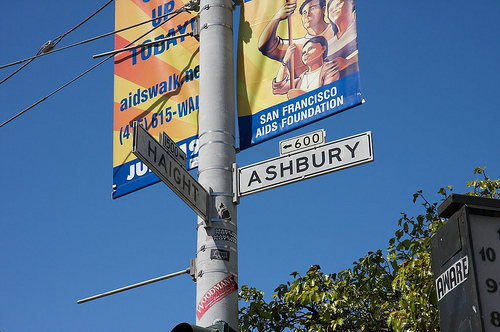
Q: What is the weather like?
A: It is clear.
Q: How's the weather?
A: It is clear.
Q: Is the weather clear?
A: Yes, it is clear.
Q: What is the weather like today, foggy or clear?
A: It is clear.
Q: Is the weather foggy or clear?
A: It is clear.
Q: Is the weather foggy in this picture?
A: No, it is clear.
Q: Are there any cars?
A: No, there are no cars.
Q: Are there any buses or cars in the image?
A: No, there are no cars or buses.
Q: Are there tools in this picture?
A: No, there are no tools.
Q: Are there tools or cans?
A: No, there are no tools or cans.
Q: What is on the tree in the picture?
A: The leaves are on the tree.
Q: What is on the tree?
A: The leaves are on the tree.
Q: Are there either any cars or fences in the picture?
A: No, there are no cars or fences.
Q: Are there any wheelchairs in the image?
A: No, there are no wheelchairs.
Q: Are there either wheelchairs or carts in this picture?
A: No, there are no wheelchairs or carts.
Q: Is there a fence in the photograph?
A: No, there are no fences.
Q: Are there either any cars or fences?
A: No, there are no fences or cars.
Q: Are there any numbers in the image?
A: Yes, there are numbers.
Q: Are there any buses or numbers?
A: Yes, there are numbers.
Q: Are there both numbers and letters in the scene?
A: Yes, there are both numbers and letters.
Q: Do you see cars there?
A: No, there are no cars.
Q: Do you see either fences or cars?
A: No, there are no cars or fences.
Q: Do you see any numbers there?
A: Yes, there are numbers.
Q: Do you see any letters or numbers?
A: Yes, there are numbers.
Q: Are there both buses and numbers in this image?
A: No, there are numbers but no buses.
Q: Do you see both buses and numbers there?
A: No, there are numbers but no buses.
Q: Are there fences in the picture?
A: No, there are no fences.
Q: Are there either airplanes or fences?
A: No, there are no fences or airplanes.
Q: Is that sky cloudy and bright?
A: No, the sky is bright but clear.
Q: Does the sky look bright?
A: Yes, the sky is bright.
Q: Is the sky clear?
A: Yes, the sky is clear.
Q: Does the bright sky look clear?
A: Yes, the sky is clear.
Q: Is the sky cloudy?
A: No, the sky is clear.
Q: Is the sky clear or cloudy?
A: The sky is clear.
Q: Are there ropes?
A: No, there are no ropes.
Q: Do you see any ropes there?
A: No, there are no ropes.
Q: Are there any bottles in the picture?
A: No, there are no bottles.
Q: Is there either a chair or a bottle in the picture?
A: No, there are no bottles or chairs.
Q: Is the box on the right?
A: Yes, the box is on the right of the image.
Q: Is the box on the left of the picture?
A: No, the box is on the right of the image.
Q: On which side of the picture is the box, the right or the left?
A: The box is on the right of the image.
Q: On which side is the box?
A: The box is on the right of the image.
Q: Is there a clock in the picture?
A: Yes, there is a clock.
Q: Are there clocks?
A: Yes, there is a clock.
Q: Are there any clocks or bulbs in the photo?
A: Yes, there is a clock.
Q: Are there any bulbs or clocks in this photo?
A: Yes, there is a clock.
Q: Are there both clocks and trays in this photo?
A: No, there is a clock but no trays.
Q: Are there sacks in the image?
A: No, there are no sacks.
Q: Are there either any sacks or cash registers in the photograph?
A: No, there are no sacks or cash registers.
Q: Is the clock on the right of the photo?
A: Yes, the clock is on the right of the image.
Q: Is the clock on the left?
A: No, the clock is on the right of the image.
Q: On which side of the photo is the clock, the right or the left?
A: The clock is on the right of the image.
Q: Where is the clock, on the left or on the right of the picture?
A: The clock is on the right of the image.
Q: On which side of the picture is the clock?
A: The clock is on the right of the image.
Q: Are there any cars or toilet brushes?
A: No, there are no cars or toilet brushes.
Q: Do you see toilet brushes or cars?
A: No, there are no cars or toilet brushes.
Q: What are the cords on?
A: The cords are on the pole.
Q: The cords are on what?
A: The cords are on the pole.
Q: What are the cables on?
A: The cords are on the pole.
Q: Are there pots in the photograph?
A: No, there are no pots.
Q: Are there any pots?
A: No, there are no pots.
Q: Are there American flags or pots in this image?
A: No, there are no pots or American flags.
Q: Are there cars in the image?
A: No, there are no cars.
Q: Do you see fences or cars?
A: No, there are no cars or fences.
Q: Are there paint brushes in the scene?
A: No, there are no paint brushes.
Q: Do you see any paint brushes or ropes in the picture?
A: No, there are no paint brushes or ropes.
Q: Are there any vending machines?
A: No, there are no vending machines.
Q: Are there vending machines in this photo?
A: No, there are no vending machines.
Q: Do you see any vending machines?
A: No, there are no vending machines.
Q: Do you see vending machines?
A: No, there are no vending machines.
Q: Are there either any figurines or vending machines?
A: No, there are no vending machines or figurines.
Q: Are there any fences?
A: No, there are no fences.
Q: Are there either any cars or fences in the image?
A: No, there are no fences or cars.